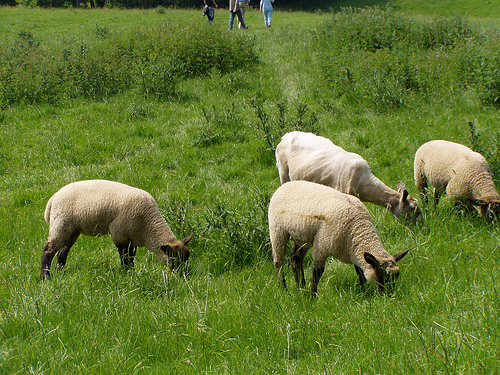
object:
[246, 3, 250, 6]
frisbee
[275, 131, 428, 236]
sheep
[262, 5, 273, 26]
jeans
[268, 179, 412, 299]
sheep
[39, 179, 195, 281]
sheep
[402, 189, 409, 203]
ear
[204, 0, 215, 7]
shirt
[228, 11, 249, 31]
jeans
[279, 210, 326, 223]
mark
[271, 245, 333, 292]
legs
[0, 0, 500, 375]
field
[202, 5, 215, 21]
jacket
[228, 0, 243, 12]
shirt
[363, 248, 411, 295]
head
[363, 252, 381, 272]
ear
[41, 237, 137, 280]
legs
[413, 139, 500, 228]
sheep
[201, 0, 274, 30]
people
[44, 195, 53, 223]
tail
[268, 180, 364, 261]
body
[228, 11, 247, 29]
legs